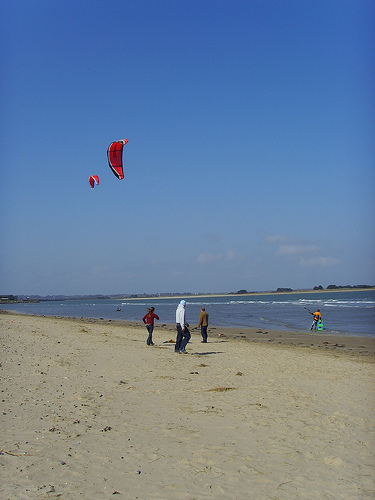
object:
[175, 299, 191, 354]
man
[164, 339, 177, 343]
kite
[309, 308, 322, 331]
man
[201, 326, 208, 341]
jeans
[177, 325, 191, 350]
jeans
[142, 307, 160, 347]
girl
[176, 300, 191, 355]
person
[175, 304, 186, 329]
hoodie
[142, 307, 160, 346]
boy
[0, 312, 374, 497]
beach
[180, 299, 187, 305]
hat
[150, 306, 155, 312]
head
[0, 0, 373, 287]
sky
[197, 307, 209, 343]
man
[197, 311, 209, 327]
jacket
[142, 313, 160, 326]
shirt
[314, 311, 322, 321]
shirt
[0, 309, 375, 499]
sand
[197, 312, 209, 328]
sweater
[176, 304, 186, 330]
shirt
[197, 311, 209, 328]
shirt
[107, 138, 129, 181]
kite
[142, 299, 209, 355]
three people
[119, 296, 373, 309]
waves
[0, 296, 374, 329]
water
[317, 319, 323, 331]
treeskiteboard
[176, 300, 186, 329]
sweatshirt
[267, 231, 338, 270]
clouds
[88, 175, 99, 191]
kite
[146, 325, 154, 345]
jeans